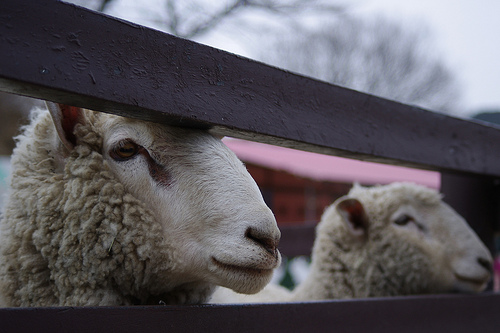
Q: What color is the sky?
A: Gray.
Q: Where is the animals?
A: At fence.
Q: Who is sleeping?
A: No one.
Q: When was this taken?
A: Day time.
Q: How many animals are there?
A: Two.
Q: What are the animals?
A: Sheep.